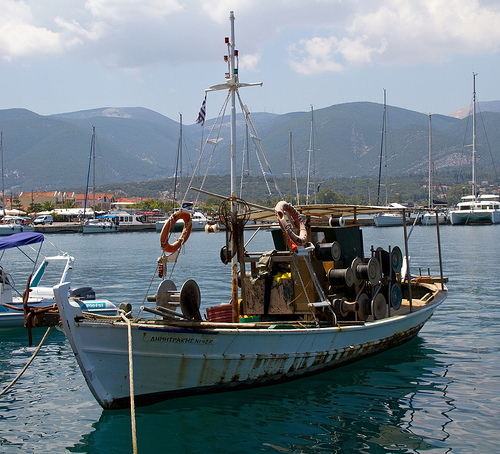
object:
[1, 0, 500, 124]
sky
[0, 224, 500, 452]
water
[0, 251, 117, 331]
boats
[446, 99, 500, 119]
moutains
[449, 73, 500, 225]
boat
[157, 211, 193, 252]
lifesaver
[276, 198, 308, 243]
equipment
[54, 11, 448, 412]
boat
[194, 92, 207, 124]
flag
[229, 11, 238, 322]
post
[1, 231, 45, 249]
roof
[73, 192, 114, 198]
roofs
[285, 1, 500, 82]
clouds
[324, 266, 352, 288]
spools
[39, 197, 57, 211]
trees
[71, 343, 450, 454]
reflection